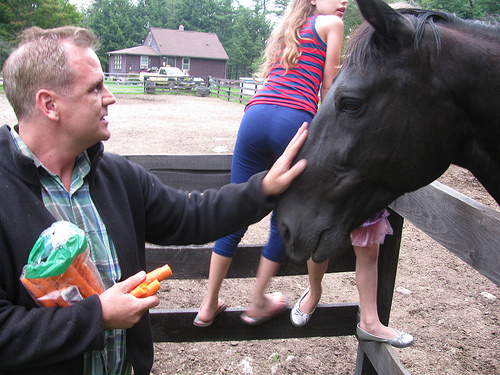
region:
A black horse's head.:
[273, 3, 497, 270]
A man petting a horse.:
[8, 3, 418, 366]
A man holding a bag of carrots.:
[3, 27, 218, 373]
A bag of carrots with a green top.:
[2, 206, 184, 308]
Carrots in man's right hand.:
[82, 242, 190, 359]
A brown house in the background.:
[101, 13, 236, 96]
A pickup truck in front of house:
[132, 51, 202, 100]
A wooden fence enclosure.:
[143, 142, 498, 369]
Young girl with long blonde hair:
[249, 5, 344, 112]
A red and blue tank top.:
[255, 12, 345, 107]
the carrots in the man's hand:
[125, 262, 175, 297]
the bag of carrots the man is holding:
[26, 221, 99, 303]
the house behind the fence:
[101, 30, 232, 80]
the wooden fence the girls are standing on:
[131, 138, 444, 369]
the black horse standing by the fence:
[261, 7, 496, 270]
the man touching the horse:
[10, 24, 273, 370]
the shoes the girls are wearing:
[200, 295, 417, 352]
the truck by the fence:
[138, 65, 183, 85]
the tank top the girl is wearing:
[241, 13, 344, 118]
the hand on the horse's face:
[260, 111, 308, 200]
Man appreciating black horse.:
[6, 21, 483, 263]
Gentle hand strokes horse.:
[185, 118, 328, 216]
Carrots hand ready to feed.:
[72, 252, 188, 358]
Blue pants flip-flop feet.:
[194, 108, 289, 332]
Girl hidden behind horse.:
[291, 132, 429, 347]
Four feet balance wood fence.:
[177, 250, 434, 355]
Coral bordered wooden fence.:
[127, 74, 257, 154]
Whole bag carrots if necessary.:
[9, 217, 114, 340]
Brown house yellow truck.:
[96, 18, 233, 97]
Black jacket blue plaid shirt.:
[15, 159, 192, 275]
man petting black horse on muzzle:
[27, 16, 468, 312]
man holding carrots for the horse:
[22, 203, 179, 329]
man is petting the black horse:
[261, 81, 409, 214]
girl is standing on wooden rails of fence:
[226, 2, 350, 134]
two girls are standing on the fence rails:
[188, 272, 415, 361]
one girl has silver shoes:
[284, 290, 421, 359]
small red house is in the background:
[105, 11, 225, 96]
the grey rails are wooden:
[321, 195, 491, 362]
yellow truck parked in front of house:
[136, 65, 193, 94]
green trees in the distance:
[76, 0, 258, 42]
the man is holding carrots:
[6, 26, 181, 342]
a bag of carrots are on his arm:
[3, 210, 138, 373]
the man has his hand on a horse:
[35, 26, 496, 271]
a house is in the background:
[100, 22, 230, 88]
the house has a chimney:
[175, 21, 186, 31]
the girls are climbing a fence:
[182, 0, 440, 365]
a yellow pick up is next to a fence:
[135, 61, 188, 87]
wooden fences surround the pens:
[1, 66, 486, 363]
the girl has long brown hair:
[250, 0, 343, 80]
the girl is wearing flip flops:
[190, 292, 288, 332]